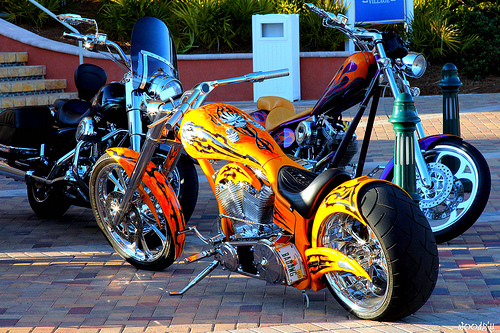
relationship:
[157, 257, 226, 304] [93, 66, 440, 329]
kickstand on motorcycle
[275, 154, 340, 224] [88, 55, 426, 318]
seat on motorcycle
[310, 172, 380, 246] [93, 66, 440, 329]
fender on motorcycle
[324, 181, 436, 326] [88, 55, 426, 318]
tire on motorcycle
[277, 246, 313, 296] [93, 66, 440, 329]
license plate on motorcycle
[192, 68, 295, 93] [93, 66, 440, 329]
handlebar on motorcycle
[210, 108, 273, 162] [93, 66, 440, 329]
design on motorcycle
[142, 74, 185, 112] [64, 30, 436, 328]
light on motorcycle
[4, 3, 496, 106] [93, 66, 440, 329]
trees behind motorcycle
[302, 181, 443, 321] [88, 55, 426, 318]
tire on motorcycle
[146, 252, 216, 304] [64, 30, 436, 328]
kickstand on motorcycle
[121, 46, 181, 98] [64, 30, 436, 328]
windshield on motorcycle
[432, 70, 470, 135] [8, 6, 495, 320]
pole near motorcycles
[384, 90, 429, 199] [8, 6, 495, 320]
pole near motorcycles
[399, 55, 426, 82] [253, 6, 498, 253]
headlight on motorcycle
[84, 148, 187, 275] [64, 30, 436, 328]
front tire on motorcycle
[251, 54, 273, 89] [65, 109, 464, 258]
post box in background